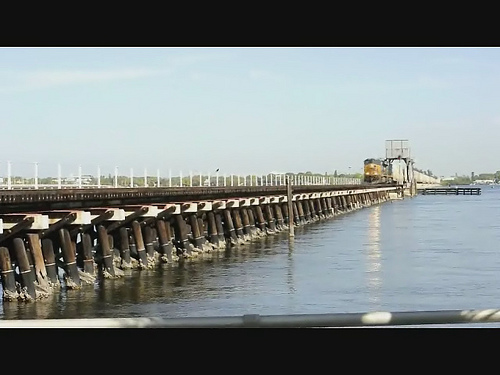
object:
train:
[364, 155, 445, 185]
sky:
[0, 48, 499, 176]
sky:
[135, 58, 345, 143]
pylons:
[0, 163, 361, 192]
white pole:
[56, 163, 59, 189]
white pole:
[7, 160, 12, 191]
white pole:
[115, 166, 117, 188]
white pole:
[189, 171, 191, 186]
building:
[43, 162, 96, 184]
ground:
[237, 197, 349, 252]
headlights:
[364, 171, 379, 176]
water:
[333, 207, 496, 302]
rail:
[0, 247, 16, 299]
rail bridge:
[0, 185, 391, 300]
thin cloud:
[6, 62, 173, 83]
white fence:
[230, 173, 233, 187]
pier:
[0, 159, 357, 327]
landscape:
[437, 172, 500, 186]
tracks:
[0, 183, 391, 206]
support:
[118, 225, 130, 274]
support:
[13, 237, 36, 302]